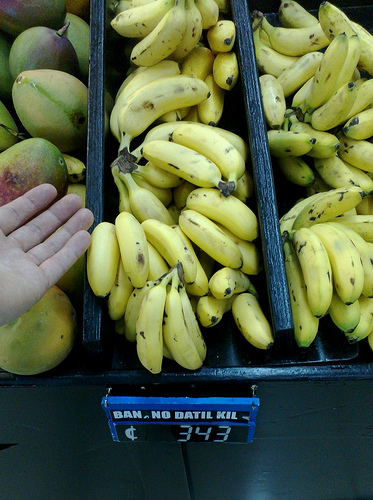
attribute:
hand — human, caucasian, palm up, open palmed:
[0, 182, 96, 329]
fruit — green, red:
[1, 137, 69, 237]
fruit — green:
[66, 183, 87, 210]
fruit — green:
[55, 250, 87, 296]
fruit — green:
[1, 284, 77, 375]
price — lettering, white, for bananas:
[177, 424, 232, 444]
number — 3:
[176, 425, 192, 444]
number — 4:
[195, 425, 211, 441]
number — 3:
[213, 423, 231, 445]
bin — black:
[84, 0, 294, 375]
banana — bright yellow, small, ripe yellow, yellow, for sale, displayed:
[180, 188, 257, 243]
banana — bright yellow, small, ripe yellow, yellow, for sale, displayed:
[168, 123, 245, 191]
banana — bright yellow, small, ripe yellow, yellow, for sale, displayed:
[205, 19, 236, 53]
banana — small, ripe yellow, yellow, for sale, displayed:
[118, 74, 212, 158]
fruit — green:
[12, 69, 88, 155]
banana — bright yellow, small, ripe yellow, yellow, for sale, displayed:
[129, 0, 187, 67]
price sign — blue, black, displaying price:
[100, 384, 260, 446]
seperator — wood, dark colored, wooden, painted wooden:
[80, 0, 105, 344]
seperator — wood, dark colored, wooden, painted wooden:
[229, 0, 294, 338]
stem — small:
[227, 173, 239, 193]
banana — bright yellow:
[162, 267, 204, 372]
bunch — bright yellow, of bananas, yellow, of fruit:
[111, 155, 184, 227]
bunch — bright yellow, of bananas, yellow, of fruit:
[110, 58, 212, 164]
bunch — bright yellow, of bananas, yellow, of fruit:
[110, 0, 220, 68]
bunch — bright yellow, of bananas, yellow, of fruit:
[282, 220, 372, 351]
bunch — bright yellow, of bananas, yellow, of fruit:
[123, 261, 207, 375]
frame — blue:
[99, 397, 260, 443]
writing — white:
[112, 410, 239, 421]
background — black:
[109, 409, 251, 423]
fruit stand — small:
[0, 0, 372, 500]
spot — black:
[172, 84, 184, 93]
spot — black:
[120, 132, 126, 137]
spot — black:
[129, 93, 154, 114]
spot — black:
[153, 93, 165, 99]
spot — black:
[188, 84, 198, 92]